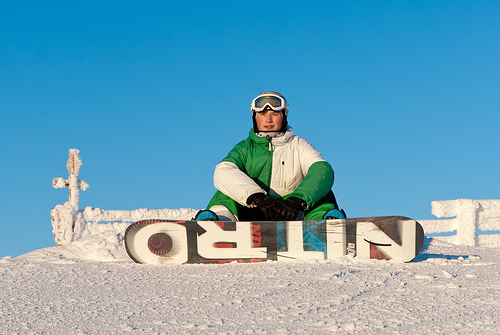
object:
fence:
[50, 148, 500, 247]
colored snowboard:
[124, 215, 424, 265]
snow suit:
[189, 125, 347, 222]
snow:
[0, 147, 500, 335]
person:
[190, 91, 346, 222]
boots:
[322, 208, 347, 220]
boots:
[195, 209, 219, 220]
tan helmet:
[251, 91, 289, 116]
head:
[250, 91, 289, 135]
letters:
[132, 219, 415, 266]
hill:
[0, 244, 498, 335]